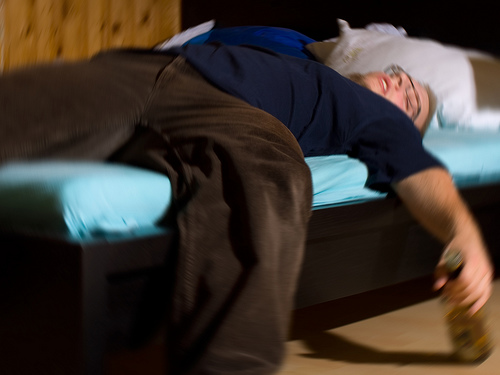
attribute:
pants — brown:
[8, 42, 325, 368]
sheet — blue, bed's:
[7, 125, 497, 239]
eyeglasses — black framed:
[384, 61, 425, 120]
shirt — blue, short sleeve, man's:
[152, 31, 445, 184]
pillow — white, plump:
[305, 8, 500, 136]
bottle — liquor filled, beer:
[442, 251, 500, 365]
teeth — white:
[381, 76, 389, 95]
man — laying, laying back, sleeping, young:
[10, 29, 500, 365]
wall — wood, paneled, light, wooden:
[8, 0, 186, 68]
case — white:
[303, 21, 500, 131]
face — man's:
[355, 59, 431, 131]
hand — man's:
[436, 231, 498, 313]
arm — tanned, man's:
[389, 168, 480, 242]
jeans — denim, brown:
[0, 46, 311, 373]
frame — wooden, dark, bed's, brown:
[11, 187, 500, 365]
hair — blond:
[420, 82, 446, 138]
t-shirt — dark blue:
[146, 38, 446, 185]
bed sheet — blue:
[6, 81, 497, 230]